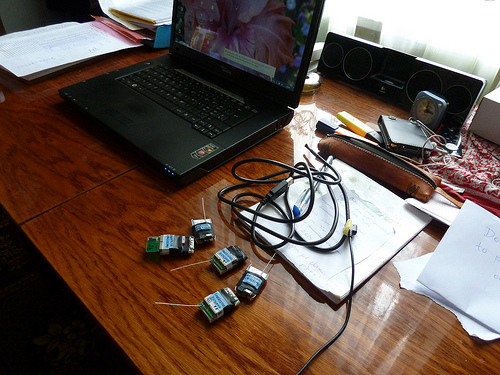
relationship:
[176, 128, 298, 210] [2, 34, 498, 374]
shadow cast on desk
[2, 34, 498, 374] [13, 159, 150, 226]
desk has crack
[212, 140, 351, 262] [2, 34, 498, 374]
cable sitting on desk